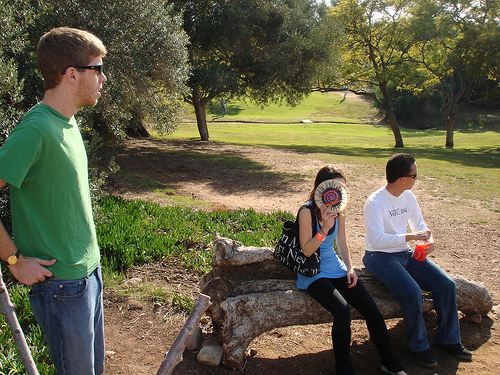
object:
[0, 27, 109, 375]
man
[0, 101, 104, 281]
shirt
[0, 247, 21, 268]
wach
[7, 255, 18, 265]
face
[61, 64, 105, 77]
sunglasses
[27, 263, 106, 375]
jeans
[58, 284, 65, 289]
rivets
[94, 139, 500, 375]
path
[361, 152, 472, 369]
man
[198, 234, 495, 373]
log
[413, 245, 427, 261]
label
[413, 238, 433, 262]
bottle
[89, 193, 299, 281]
grass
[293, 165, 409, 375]
person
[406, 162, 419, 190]
face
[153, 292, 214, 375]
stump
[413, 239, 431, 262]
gatorade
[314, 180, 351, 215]
frisbee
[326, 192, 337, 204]
swirls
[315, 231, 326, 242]
braclets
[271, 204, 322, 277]
bag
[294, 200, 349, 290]
shirt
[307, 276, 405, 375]
pants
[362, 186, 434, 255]
shirt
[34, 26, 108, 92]
hair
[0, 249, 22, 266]
watch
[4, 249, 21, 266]
band